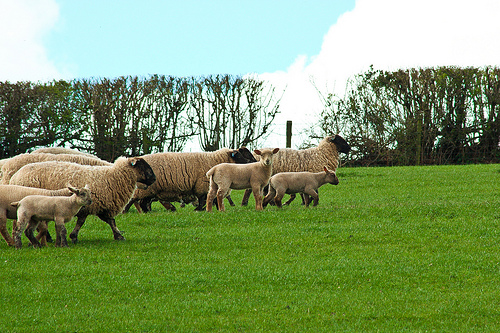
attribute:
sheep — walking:
[269, 167, 339, 211]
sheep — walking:
[205, 149, 278, 210]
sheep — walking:
[12, 186, 91, 245]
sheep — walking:
[271, 135, 349, 172]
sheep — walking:
[10, 159, 157, 241]